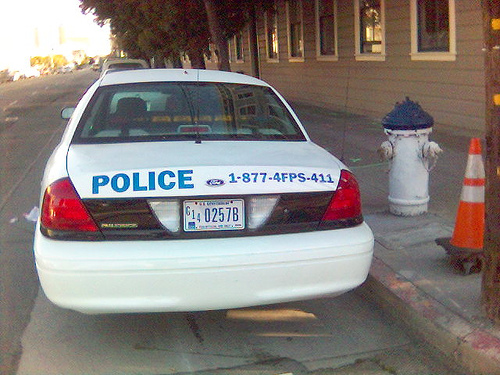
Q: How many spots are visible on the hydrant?
A: Two.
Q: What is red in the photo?
A: Tail lights.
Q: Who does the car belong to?
A: Police.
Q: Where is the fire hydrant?
A: To the right of the car.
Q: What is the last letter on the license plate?
A: B.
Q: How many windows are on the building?
A: Six.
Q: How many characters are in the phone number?
A: Eleven.